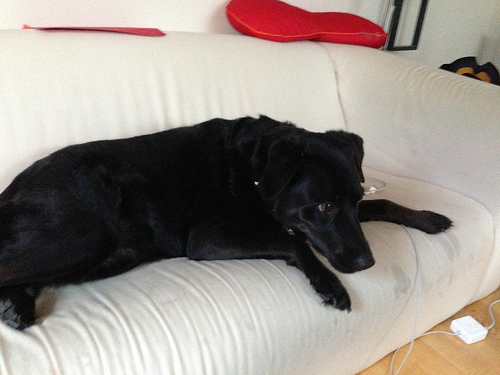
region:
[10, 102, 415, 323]
The dog is black.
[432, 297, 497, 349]
The charger is white.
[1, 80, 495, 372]
The couch is white.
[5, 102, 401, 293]
The dog is laying on a couch.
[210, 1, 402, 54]
The pillow is red.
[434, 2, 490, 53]
The wall is white.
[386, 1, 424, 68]
The mirror frame is black.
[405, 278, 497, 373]
The floor is wood.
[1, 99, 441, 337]
There is one dog.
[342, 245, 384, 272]
The dogs nose is black.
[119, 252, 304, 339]
The couch is white.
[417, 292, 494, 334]
The chord is white.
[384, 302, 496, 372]
There is one computer charger.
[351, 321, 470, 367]
The floor is wood.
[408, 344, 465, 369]
The wood is brown.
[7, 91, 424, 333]
large black dog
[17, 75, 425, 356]
large black dog lying on white couch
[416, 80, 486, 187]
solid white couch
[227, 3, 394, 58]
red pillow on top of couch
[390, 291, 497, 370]
white electrical wire on floor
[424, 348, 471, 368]
light brown wood floor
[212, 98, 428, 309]
black dog with eyes open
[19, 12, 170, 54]
pink item on top of couch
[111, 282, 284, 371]
row of wrinkles in fabric of couch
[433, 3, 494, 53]
solid white walls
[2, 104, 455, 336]
There is a black dog on the couch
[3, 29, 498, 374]
The couch is white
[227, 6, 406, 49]
There is a red pillow on the couch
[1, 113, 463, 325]
The dog is laying down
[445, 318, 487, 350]
There is a white box on the floor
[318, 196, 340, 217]
The dog has brown eyes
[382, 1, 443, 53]
There is a mirror in the background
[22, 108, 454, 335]
The dog looks sad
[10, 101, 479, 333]
The dog is resting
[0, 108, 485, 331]
The black dog likes laying on the couch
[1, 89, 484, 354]
the dog is black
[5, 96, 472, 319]
the dog is laying on the couch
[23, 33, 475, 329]
the couch is white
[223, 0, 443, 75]
the pillow is red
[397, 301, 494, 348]
a cord is on the floor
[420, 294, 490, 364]
the cord is white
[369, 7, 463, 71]
a mirror is on the wall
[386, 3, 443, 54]
the mirror is black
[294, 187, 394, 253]
the dog's eye is brown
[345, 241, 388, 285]
the dog's nose is black